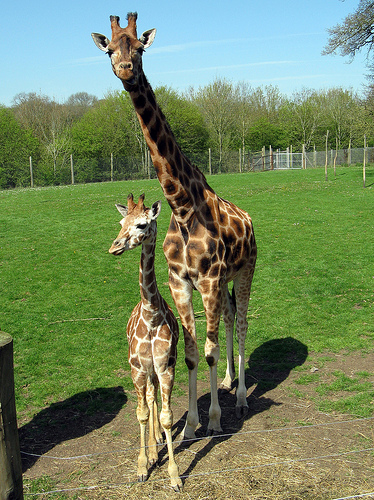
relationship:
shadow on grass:
[141, 336, 310, 487] [2, 166, 372, 498]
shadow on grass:
[15, 382, 127, 473] [2, 166, 372, 498]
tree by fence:
[0, 106, 43, 189] [2, 140, 373, 190]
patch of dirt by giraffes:
[19, 355, 374, 498] [90, 8, 258, 494]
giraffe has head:
[92, 11, 258, 441] [93, 10, 157, 81]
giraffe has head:
[110, 193, 183, 496] [106, 190, 162, 258]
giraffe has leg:
[92, 11, 258, 441] [230, 256, 255, 422]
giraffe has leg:
[92, 11, 258, 441] [215, 282, 236, 394]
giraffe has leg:
[92, 11, 258, 441] [168, 273, 201, 444]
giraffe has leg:
[92, 11, 258, 441] [197, 278, 224, 439]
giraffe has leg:
[110, 193, 183, 496] [144, 377, 160, 465]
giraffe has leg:
[110, 193, 183, 496] [134, 380, 150, 486]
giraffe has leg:
[110, 193, 183, 496] [158, 364, 186, 494]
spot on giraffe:
[131, 95, 147, 112] [92, 11, 258, 441]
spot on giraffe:
[147, 88, 160, 111] [92, 11, 258, 441]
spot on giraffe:
[137, 104, 155, 128] [92, 11, 258, 441]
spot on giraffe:
[156, 106, 168, 124] [92, 11, 258, 441]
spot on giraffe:
[143, 117, 164, 146] [92, 11, 258, 441]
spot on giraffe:
[156, 132, 171, 161] [92, 11, 258, 441]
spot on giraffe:
[165, 134, 177, 159] [92, 11, 258, 441]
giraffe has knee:
[92, 11, 258, 441] [202, 338, 220, 368]